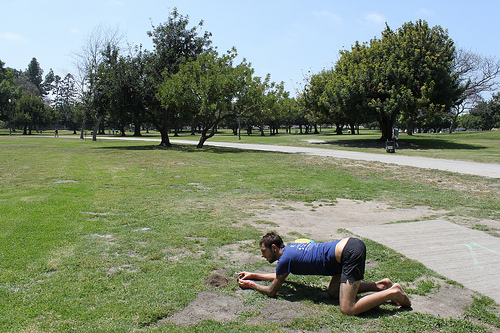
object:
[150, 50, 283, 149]
tree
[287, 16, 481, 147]
tree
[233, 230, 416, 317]
man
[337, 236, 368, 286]
shorts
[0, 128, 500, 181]
pathway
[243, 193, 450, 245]
spot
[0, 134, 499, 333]
grass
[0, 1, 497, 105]
sky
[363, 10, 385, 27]
cloud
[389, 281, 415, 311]
foot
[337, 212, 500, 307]
walkway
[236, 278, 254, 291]
hand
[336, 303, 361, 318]
knee